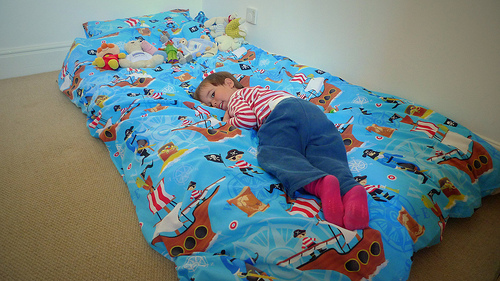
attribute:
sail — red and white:
[143, 170, 178, 222]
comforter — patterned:
[48, 5, 499, 277]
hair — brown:
[197, 64, 238, 86]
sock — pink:
[341, 182, 369, 232]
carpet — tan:
[4, 77, 160, 279]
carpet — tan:
[401, 198, 498, 275]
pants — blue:
[256, 97, 363, 199]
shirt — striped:
[225, 85, 295, 128]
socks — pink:
[306, 172, 369, 227]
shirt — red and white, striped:
[227, 83, 291, 131]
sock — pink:
[301, 172, 343, 227]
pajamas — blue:
[258, 100, 353, 189]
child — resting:
[198, 71, 370, 226]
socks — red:
[312, 173, 376, 235]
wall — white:
[2, 0, 203, 80]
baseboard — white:
[0, 44, 77, 80]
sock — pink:
[308, 167, 346, 232]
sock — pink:
[343, 182, 373, 234]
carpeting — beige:
[45, 170, 111, 260]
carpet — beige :
[0, 63, 494, 276]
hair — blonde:
[195, 68, 244, 102]